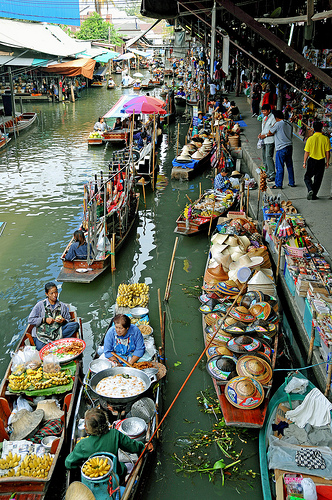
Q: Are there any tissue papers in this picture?
A: No, there are no tissue papers.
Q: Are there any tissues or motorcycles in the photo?
A: No, there are no tissues or motorcycles.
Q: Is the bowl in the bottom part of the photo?
A: Yes, the bowl is in the bottom of the image.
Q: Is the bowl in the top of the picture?
A: No, the bowl is in the bottom of the image.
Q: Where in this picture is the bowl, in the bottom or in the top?
A: The bowl is in the bottom of the image.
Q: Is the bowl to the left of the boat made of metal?
A: Yes, the bowl is made of metal.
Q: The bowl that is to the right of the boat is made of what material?
A: The bowl is made of metal.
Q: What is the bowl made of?
A: The bowl is made of metal.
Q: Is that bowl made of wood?
A: No, the bowl is made of metal.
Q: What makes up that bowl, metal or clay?
A: The bowl is made of metal.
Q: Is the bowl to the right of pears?
A: No, the bowl is to the right of the bananas.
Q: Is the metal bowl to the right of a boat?
A: Yes, the bowl is to the right of a boat.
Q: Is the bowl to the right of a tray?
A: No, the bowl is to the right of a boat.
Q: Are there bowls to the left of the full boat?
A: Yes, there is a bowl to the left of the boat.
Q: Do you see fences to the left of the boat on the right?
A: No, there is a bowl to the left of the boat.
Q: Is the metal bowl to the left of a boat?
A: Yes, the bowl is to the left of a boat.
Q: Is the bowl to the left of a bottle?
A: No, the bowl is to the left of a boat.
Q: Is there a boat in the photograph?
A: Yes, there is a boat.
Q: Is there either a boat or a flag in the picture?
A: Yes, there is a boat.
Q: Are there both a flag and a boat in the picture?
A: No, there is a boat but no flags.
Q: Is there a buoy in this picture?
A: No, there are no buoys.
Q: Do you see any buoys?
A: No, there are no buoys.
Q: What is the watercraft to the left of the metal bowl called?
A: The watercraft is a boat.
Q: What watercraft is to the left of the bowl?
A: The watercraft is a boat.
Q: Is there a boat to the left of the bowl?
A: Yes, there is a boat to the left of the bowl.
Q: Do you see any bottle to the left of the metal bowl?
A: No, there is a boat to the left of the bowl.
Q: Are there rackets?
A: No, there are no rackets.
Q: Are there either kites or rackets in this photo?
A: No, there are no rackets or kites.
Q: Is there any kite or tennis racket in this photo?
A: No, there are no rackets or kites.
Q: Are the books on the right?
A: Yes, the books are on the right of the image.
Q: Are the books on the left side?
A: No, the books are on the right of the image.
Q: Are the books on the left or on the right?
A: The books are on the right of the image.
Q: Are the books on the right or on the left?
A: The books are on the right of the image.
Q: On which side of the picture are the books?
A: The books are on the right of the image.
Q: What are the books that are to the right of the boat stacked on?
A: The books are stacked on the pier.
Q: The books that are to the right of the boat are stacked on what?
A: The books are stacked on the pier.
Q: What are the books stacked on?
A: The books are stacked on the pier.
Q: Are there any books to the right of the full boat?
A: Yes, there are books to the right of the boat.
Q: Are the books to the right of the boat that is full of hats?
A: Yes, the books are to the right of the boat.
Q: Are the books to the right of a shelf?
A: No, the books are to the right of the boat.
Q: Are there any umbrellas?
A: Yes, there are umbrellas.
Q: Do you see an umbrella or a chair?
A: Yes, there are umbrellas.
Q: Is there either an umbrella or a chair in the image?
A: Yes, there are umbrellas.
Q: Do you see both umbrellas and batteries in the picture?
A: No, there are umbrellas but no batteries.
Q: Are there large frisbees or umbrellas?
A: Yes, there are large umbrellas.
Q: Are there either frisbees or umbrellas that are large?
A: Yes, the umbrellas are large.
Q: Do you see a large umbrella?
A: Yes, there are large umbrellas.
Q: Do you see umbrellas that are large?
A: Yes, there are umbrellas that are large.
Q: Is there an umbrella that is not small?
A: Yes, there are large umbrellas.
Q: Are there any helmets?
A: No, there are no helmets.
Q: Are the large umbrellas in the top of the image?
A: Yes, the umbrellas are in the top of the image.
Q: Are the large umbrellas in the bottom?
A: No, the umbrellas are in the top of the image.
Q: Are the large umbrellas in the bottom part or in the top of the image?
A: The umbrellas are in the top of the image.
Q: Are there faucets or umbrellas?
A: Yes, there are umbrellas.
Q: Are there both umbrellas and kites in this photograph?
A: No, there are umbrellas but no kites.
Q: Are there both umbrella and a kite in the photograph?
A: No, there are umbrellas but no kites.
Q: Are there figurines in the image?
A: No, there are no figurines.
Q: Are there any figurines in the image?
A: No, there are no figurines.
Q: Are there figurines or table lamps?
A: No, there are no figurines or table lamps.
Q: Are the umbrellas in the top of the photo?
A: Yes, the umbrellas are in the top of the image.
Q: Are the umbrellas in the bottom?
A: No, the umbrellas are in the top of the image.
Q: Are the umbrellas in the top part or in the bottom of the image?
A: The umbrellas are in the top of the image.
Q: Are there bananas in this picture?
A: Yes, there are bananas.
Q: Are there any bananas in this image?
A: Yes, there are bananas.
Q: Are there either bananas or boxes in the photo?
A: Yes, there are bananas.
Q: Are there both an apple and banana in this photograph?
A: No, there are bananas but no apples.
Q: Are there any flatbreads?
A: No, there are no flatbreads.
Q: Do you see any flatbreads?
A: No, there are no flatbreads.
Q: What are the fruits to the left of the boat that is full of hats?
A: The fruits are bananas.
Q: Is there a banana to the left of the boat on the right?
A: Yes, there are bananas to the left of the boat.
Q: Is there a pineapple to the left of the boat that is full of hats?
A: No, there are bananas to the left of the boat.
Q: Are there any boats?
A: Yes, there is a boat.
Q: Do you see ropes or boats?
A: Yes, there is a boat.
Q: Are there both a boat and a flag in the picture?
A: No, there is a boat but no flags.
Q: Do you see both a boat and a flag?
A: No, there is a boat but no flags.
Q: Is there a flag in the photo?
A: No, there are no flags.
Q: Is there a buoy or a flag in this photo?
A: No, there are no flags or buoys.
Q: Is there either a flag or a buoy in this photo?
A: No, there are no flags or buoys.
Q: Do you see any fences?
A: No, there are no fences.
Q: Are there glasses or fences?
A: No, there are no fences or glasses.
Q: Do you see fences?
A: No, there are no fences.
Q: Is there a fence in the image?
A: No, there are no fences.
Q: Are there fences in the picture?
A: No, there are no fences.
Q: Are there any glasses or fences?
A: No, there are no fences or glasses.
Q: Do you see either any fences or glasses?
A: No, there are no fences or glasses.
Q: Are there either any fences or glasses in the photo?
A: No, there are no fences or glasses.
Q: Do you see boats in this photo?
A: Yes, there is a boat.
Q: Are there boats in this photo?
A: Yes, there is a boat.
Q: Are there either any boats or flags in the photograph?
A: Yes, there is a boat.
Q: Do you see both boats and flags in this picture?
A: No, there is a boat but no flags.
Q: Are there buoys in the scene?
A: No, there are no buoys.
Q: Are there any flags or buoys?
A: No, there are no buoys or flags.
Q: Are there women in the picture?
A: Yes, there is a woman.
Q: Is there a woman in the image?
A: Yes, there is a woman.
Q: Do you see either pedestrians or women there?
A: Yes, there is a woman.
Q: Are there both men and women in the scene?
A: Yes, there are both a woman and a man.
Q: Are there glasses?
A: No, there are no glasses.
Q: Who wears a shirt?
A: The woman wears a shirt.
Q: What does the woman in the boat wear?
A: The woman wears a shirt.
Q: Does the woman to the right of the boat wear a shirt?
A: Yes, the woman wears a shirt.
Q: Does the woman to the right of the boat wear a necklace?
A: No, the woman wears a shirt.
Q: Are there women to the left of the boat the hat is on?
A: Yes, there is a woman to the left of the boat.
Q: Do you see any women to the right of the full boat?
A: No, the woman is to the left of the boat.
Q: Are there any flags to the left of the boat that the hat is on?
A: No, there is a woman to the left of the boat.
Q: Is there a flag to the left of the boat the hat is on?
A: No, there is a woman to the left of the boat.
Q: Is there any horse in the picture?
A: No, there are no horses.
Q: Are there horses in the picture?
A: No, there are no horses.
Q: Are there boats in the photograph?
A: Yes, there is a boat.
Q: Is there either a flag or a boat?
A: Yes, there is a boat.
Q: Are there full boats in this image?
A: Yes, there is a full boat.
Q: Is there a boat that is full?
A: Yes, there is a boat that is full.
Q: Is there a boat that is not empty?
A: Yes, there is an full boat.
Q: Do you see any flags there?
A: No, there are no flags.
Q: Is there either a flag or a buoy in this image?
A: No, there are no flags or buoys.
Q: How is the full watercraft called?
A: The watercraft is a boat.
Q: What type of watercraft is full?
A: The watercraft is a boat.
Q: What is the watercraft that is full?
A: The watercraft is a boat.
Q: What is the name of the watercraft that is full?
A: The watercraft is a boat.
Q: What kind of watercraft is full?
A: The watercraft is a boat.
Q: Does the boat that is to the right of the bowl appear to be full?
A: Yes, the boat is full.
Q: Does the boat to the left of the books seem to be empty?
A: No, the boat is full.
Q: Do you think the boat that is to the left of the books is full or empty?
A: The boat is full.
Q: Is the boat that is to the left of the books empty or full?
A: The boat is full.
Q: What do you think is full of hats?
A: The boat is full of hats.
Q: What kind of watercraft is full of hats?
A: The watercraft is a boat.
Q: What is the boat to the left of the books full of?
A: The boat is full of hats.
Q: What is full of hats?
A: The boat is full of hats.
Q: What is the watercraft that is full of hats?
A: The watercraft is a boat.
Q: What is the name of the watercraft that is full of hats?
A: The watercraft is a boat.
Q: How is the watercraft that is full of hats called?
A: The watercraft is a boat.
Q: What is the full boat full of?
A: The boat is full of hats.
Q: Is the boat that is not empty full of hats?
A: Yes, the boat is full of hats.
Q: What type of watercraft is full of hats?
A: The watercraft is a boat.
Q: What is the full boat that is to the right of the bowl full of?
A: The boat is full of hats.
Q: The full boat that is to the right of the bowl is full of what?
A: The boat is full of hats.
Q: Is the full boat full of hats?
A: Yes, the boat is full of hats.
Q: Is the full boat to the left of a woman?
A: No, the boat is to the right of a woman.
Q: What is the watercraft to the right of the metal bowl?
A: The watercraft is a boat.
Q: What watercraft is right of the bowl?
A: The watercraft is a boat.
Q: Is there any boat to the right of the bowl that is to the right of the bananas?
A: Yes, there is a boat to the right of the bowl.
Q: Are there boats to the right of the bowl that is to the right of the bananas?
A: Yes, there is a boat to the right of the bowl.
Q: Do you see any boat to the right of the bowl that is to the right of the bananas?
A: Yes, there is a boat to the right of the bowl.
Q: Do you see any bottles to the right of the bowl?
A: No, there is a boat to the right of the bowl.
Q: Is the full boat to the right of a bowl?
A: Yes, the boat is to the right of a bowl.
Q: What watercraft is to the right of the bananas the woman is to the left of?
A: The watercraft is a boat.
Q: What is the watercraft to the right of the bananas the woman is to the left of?
A: The watercraft is a boat.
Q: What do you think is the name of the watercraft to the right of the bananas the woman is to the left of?
A: The watercraft is a boat.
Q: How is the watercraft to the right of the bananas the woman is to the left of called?
A: The watercraft is a boat.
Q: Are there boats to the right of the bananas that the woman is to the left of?
A: Yes, there is a boat to the right of the bananas.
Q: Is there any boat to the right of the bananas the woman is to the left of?
A: Yes, there is a boat to the right of the bananas.